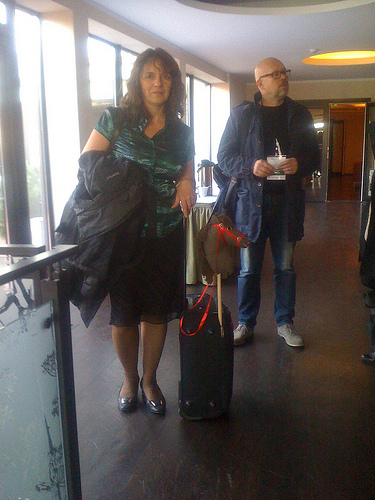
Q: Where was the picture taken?
A: On a hotel.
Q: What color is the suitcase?
A: Black.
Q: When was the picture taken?
A: In the daytime.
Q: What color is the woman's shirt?
A: Green.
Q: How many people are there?
A: 2.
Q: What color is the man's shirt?
A: Blue.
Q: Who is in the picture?
A: A couple.